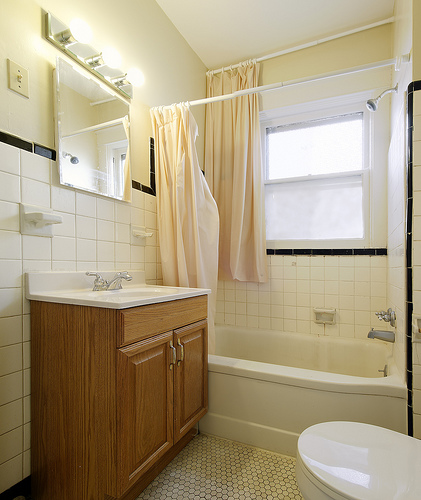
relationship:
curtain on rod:
[199, 60, 271, 288] [141, 6, 393, 124]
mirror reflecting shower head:
[53, 53, 132, 204] [61, 149, 80, 163]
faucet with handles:
[84, 269, 132, 290] [87, 270, 124, 279]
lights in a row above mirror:
[44, 9, 146, 99] [53, 53, 132, 204]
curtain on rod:
[151, 94, 226, 287] [149, 63, 419, 115]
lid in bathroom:
[296, 419, 419, 498] [0, 51, 421, 458]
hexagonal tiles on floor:
[138, 431, 299, 498] [121, 430, 307, 497]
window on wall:
[259, 110, 364, 245] [235, 29, 383, 243]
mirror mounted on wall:
[47, 51, 136, 206] [35, 180, 172, 269]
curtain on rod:
[199, 60, 271, 288] [202, 16, 402, 77]